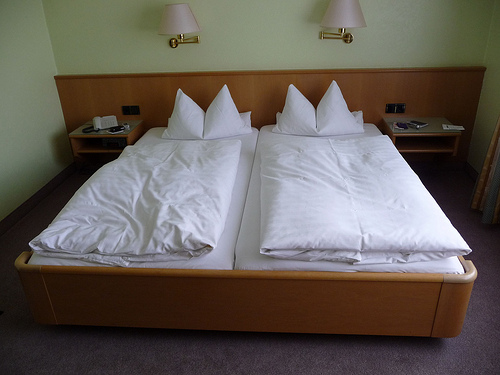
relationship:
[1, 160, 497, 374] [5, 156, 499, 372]
carpet on floor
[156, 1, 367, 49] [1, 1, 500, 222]
lights on wall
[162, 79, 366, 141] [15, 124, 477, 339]
pillows on bed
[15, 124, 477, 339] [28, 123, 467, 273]
bed has mattresses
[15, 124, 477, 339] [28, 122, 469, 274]
bed has sheets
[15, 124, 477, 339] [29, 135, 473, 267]
bed has blankets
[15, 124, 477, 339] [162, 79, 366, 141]
bed has pillows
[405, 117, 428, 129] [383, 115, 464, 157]
book on top of night stand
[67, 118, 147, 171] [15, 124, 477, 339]
night stand next to bed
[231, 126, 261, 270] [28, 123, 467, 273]
line dividing mattresses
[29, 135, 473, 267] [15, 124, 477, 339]
blankets on top of bed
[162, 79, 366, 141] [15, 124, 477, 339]
pillows on top of bed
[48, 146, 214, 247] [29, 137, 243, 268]
wrinkle in blanket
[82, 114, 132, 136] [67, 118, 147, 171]
objects on top of night stand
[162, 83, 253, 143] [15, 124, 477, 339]
pillow on bed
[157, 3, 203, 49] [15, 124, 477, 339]
light above bed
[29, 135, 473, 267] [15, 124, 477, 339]
blankets on bed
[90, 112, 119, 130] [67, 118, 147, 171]
telephone on top of night stand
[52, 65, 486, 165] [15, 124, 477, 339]
headboard behind bed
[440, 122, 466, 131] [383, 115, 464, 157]
paper on top of night stand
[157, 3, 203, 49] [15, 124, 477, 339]
light on top of bed